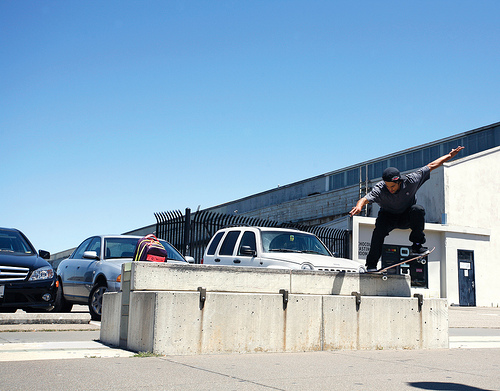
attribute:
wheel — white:
[378, 273, 390, 283]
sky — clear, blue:
[2, 2, 497, 253]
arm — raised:
[349, 185, 381, 217]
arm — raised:
[410, 144, 464, 184]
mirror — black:
[240, 246, 258, 259]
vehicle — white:
[205, 225, 366, 274]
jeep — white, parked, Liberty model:
[201, 226, 365, 275]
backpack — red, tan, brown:
[133, 234, 166, 265]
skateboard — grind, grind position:
[366, 247, 434, 280]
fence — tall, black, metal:
[152, 206, 351, 266]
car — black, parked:
[0, 228, 60, 315]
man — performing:
[349, 146, 468, 272]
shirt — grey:
[366, 167, 428, 213]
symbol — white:
[402, 189, 413, 199]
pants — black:
[366, 204, 426, 269]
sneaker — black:
[366, 265, 377, 274]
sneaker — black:
[412, 245, 423, 257]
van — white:
[201, 226, 365, 274]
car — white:
[197, 215, 364, 275]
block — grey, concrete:
[2, 304, 94, 327]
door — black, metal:
[453, 244, 480, 307]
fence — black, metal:
[150, 204, 348, 249]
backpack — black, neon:
[135, 228, 171, 262]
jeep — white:
[197, 221, 366, 270]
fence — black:
[150, 203, 351, 257]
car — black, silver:
[57, 226, 186, 318]